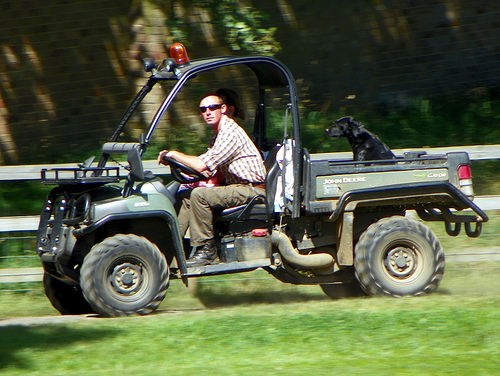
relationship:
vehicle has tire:
[30, 48, 492, 319] [357, 199, 460, 305]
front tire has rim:
[77, 232, 175, 319] [110, 258, 147, 300]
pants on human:
[171, 181, 271, 265] [155, 92, 273, 276]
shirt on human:
[226, 137, 257, 174] [158, 96, 258, 287]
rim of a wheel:
[383, 246, 418, 279] [346, 206, 451, 300]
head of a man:
[190, 93, 226, 129] [172, 87, 277, 202]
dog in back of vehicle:
[322, 112, 397, 161] [30, 48, 492, 319]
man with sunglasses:
[157, 93, 266, 265] [197, 104, 220, 111]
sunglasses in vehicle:
[197, 104, 220, 111] [30, 48, 492, 319]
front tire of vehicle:
[67, 240, 185, 324] [44, 40, 441, 317]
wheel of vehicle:
[346, 206, 451, 300] [30, 48, 492, 319]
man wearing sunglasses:
[157, 93, 266, 265] [198, 103, 225, 114]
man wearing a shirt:
[178, 115, 275, 185] [208, 125, 265, 193]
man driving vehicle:
[157, 93, 266, 265] [79, 70, 426, 308]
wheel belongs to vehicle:
[346, 206, 451, 300] [30, 48, 492, 319]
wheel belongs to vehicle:
[343, 180, 475, 310] [91, 39, 445, 338]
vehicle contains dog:
[30, 48, 492, 319] [322, 112, 397, 161]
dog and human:
[322, 112, 397, 161] [154, 92, 268, 265]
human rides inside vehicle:
[163, 94, 269, 252] [43, 39, 461, 373]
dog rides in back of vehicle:
[322, 112, 397, 161] [63, 63, 464, 306]